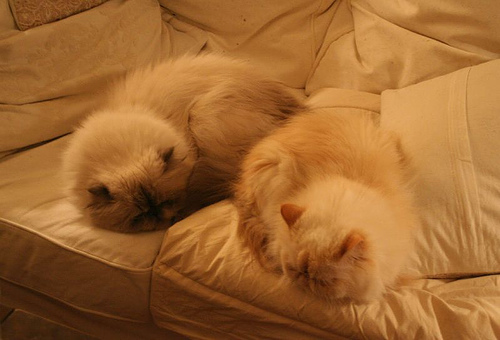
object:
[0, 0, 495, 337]
couch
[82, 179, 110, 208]
ear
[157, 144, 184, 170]
ear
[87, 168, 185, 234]
face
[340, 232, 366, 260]
ear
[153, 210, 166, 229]
nose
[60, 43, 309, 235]
kitten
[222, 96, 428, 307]
kitten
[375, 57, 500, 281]
pillow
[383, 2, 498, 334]
side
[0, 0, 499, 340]
photo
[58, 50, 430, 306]
together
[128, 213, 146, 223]
eyes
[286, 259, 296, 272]
eyes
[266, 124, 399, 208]
fur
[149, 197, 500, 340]
cushion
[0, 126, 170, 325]
cushion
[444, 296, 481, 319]
spots